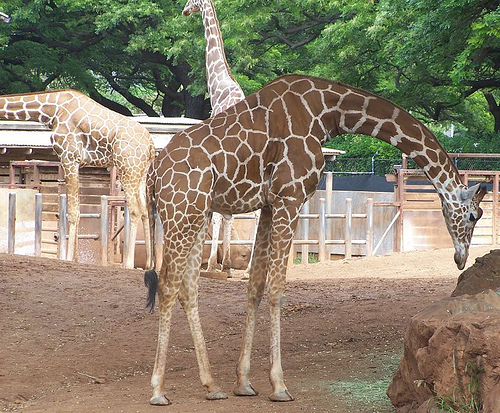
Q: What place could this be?
A: It is a pen.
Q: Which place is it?
A: It is a pen.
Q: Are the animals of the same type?
A: Yes, all the animals are giraffes.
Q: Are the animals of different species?
A: No, all the animals are giraffes.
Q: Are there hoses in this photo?
A: No, there are no hoses.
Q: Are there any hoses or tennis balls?
A: No, there are no hoses or tennis balls.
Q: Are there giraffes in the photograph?
A: Yes, there is a giraffe.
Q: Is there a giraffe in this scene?
A: Yes, there is a giraffe.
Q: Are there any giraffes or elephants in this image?
A: Yes, there is a giraffe.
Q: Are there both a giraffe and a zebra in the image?
A: No, there is a giraffe but no zebras.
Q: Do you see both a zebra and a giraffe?
A: No, there is a giraffe but no zebras.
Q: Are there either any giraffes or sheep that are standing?
A: Yes, the giraffe is standing.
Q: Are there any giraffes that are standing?
A: Yes, there is a giraffe that is standing.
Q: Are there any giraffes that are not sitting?
A: Yes, there is a giraffe that is standing.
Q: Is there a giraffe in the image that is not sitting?
A: Yes, there is a giraffe that is standing.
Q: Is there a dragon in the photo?
A: No, there are no dragons.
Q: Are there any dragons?
A: No, there are no dragons.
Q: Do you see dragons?
A: No, there are no dragons.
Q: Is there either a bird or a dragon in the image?
A: No, there are no dragons or birds.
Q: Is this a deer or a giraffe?
A: This is a giraffe.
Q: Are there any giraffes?
A: Yes, there is a giraffe.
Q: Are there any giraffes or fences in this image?
A: Yes, there is a giraffe.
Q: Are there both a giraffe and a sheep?
A: No, there is a giraffe but no sheep.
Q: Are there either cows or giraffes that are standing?
A: Yes, the giraffe is standing.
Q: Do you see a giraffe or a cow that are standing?
A: Yes, the giraffe is standing.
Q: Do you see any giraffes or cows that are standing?
A: Yes, the giraffe is standing.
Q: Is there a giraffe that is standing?
A: Yes, there is a giraffe that is standing.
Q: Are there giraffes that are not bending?
A: Yes, there is a giraffe that is standing.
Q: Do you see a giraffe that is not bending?
A: Yes, there is a giraffe that is standing .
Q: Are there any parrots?
A: No, there are no parrots.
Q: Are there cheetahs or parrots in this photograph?
A: No, there are no parrots or cheetahs.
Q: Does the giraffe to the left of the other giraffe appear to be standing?
A: Yes, the giraffe is standing.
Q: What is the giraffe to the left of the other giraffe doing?
A: The giraffe is standing.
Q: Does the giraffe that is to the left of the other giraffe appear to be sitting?
A: No, the giraffe is standing.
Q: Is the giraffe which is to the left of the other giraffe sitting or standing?
A: The giraffe is standing.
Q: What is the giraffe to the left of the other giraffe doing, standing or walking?
A: The giraffe is standing.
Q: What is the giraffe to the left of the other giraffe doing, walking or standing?
A: The giraffe is standing.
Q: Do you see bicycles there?
A: No, there are no bicycles.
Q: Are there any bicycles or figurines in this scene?
A: No, there are no bicycles or figurines.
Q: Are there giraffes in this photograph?
A: Yes, there is a giraffe.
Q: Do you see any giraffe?
A: Yes, there is a giraffe.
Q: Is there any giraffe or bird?
A: Yes, there is a giraffe.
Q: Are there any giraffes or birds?
A: Yes, there is a giraffe.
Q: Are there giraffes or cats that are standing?
A: Yes, the giraffe is standing.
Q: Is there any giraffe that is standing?
A: Yes, there is a giraffe that is standing.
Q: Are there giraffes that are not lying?
A: Yes, there is a giraffe that is standing.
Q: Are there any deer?
A: No, there are no deer.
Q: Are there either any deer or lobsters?
A: No, there are no deer or lobsters.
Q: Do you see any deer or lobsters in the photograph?
A: No, there are no deer or lobsters.